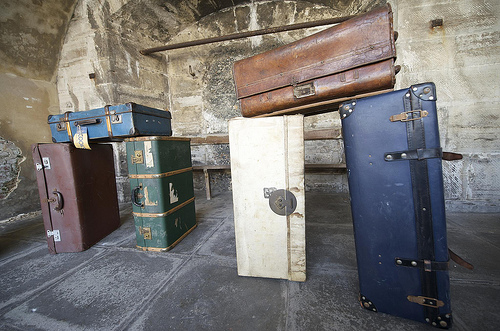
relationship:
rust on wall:
[430, 17, 444, 30] [2, 0, 498, 225]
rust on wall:
[87, 72, 99, 80] [2, 0, 498, 225]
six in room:
[27, 2, 457, 330] [2, 2, 500, 328]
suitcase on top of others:
[45, 100, 174, 148] [30, 136, 199, 256]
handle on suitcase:
[50, 188, 67, 213] [28, 141, 124, 255]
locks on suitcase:
[35, 156, 62, 241] [28, 141, 124, 255]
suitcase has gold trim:
[122, 132, 201, 255] [123, 134, 199, 253]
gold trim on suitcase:
[123, 134, 199, 253] [122, 132, 201, 255]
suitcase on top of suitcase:
[227, 5, 401, 121] [226, 114, 308, 282]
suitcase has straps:
[337, 80, 450, 329] [384, 144, 476, 275]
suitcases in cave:
[27, 2, 457, 330] [2, 2, 500, 328]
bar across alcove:
[139, 11, 358, 59] [101, 1, 391, 195]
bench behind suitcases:
[189, 126, 349, 203] [27, 2, 457, 330]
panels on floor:
[2, 186, 499, 329] [2, 186, 500, 329]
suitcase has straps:
[45, 100, 174, 148] [64, 105, 115, 143]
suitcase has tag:
[45, 100, 174, 148] [70, 128, 94, 154]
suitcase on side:
[28, 141, 124, 255] [42, 223, 124, 258]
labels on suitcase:
[143, 138, 181, 206] [122, 132, 201, 255]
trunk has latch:
[226, 112, 310, 287] [269, 188, 299, 218]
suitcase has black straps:
[337, 80, 450, 329] [384, 144, 476, 275]